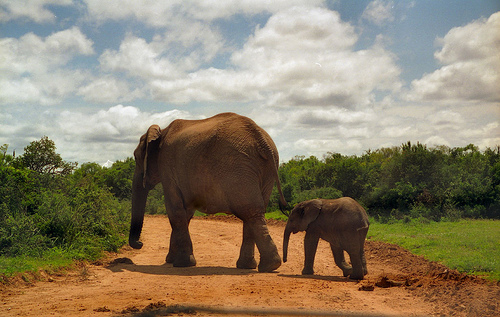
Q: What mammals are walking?
A: Elephants.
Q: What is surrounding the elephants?
A: Shrubs.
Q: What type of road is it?
A: Dirt.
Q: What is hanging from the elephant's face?
A: A trunk.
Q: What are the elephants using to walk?
A: Their legs.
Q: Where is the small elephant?
A: Behind the big one.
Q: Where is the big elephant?
A: In front.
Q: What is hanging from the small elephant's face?
A: A trunk.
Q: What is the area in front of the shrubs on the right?
A: Grass.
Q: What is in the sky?
A: Clouds.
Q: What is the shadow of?
A: Elephant.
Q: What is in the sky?
A: Clouds.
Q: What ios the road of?
A: Dirt.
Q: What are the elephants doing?
A: Standing.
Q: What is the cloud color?
A: White.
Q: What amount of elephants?
A: Two.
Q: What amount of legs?
A: Four.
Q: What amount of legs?
A: Four.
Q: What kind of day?
A: Sunny.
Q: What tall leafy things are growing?
A: Trees.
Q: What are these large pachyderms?
A: Elephants.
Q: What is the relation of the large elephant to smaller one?
A: Parent.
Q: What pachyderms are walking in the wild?
A: Elephants.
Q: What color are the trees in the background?
A: Green.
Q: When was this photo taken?
A: Day time.